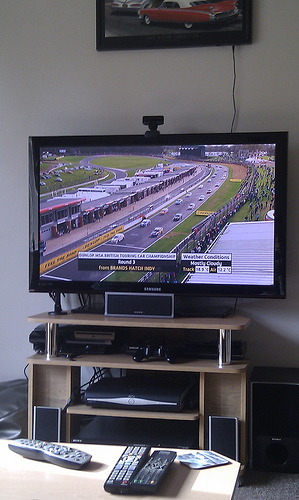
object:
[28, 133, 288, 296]
frame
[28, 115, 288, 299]
television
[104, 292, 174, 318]
speaker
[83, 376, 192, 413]
box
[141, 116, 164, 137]
camera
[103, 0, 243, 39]
picture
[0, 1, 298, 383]
wall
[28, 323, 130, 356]
system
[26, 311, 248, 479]
center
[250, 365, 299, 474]
speaker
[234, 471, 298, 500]
carpet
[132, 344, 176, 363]
controller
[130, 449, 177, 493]
control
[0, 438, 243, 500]
table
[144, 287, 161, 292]
logo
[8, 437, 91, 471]
remote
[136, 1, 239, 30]
car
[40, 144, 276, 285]
game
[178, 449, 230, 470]
coaster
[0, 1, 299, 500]
room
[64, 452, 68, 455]
button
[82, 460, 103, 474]
shadow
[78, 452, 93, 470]
head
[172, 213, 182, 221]
car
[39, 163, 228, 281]
road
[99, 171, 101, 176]
people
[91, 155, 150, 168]
grass